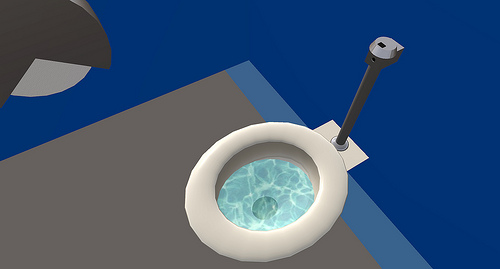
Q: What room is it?
A: It is a bathroom.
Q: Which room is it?
A: It is a bathroom.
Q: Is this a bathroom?
A: Yes, it is a bathroom.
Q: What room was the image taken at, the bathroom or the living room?
A: It was taken at the bathroom.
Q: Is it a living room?
A: No, it is a bathroom.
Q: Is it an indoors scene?
A: Yes, it is indoors.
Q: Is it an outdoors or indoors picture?
A: It is indoors.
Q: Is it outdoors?
A: No, it is indoors.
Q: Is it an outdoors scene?
A: No, it is indoors.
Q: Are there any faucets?
A: No, there are no faucets.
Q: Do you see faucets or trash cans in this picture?
A: No, there are no faucets or trash cans.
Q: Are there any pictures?
A: No, there are no pictures.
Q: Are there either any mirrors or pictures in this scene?
A: No, there are no pictures or mirrors.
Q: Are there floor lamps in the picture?
A: No, there are no floor lamps.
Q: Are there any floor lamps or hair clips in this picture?
A: No, there are no floor lamps or hair clips.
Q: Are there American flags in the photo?
A: No, there are no American flags.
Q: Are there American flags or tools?
A: No, there are no American flags or tools.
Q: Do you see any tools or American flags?
A: No, there are no American flags or tools.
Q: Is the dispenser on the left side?
A: Yes, the dispenser is on the left of the image.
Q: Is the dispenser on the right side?
A: No, the dispenser is on the left of the image.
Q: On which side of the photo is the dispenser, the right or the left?
A: The dispenser is on the left of the image.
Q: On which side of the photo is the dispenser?
A: The dispenser is on the left of the image.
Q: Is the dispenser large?
A: Yes, the dispenser is large.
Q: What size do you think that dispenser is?
A: The dispenser is large.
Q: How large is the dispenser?
A: The dispenser is large.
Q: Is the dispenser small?
A: No, the dispenser is large.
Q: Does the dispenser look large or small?
A: The dispenser is large.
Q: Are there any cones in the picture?
A: No, there are no cones.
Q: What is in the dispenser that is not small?
A: The paper is in the dispenser.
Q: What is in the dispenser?
A: The paper is in the dispenser.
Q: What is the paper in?
A: The paper is in the dispenser.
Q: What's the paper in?
A: The paper is in the dispenser.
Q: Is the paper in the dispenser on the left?
A: Yes, the paper is in the dispenser.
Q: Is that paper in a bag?
A: No, the paper is in the dispenser.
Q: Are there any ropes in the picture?
A: No, there are no ropes.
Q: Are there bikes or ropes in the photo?
A: No, there are no ropes or bikes.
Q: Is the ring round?
A: Yes, the ring is round.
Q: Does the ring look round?
A: Yes, the ring is round.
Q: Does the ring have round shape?
A: Yes, the ring is round.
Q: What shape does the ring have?
A: The ring has round shape.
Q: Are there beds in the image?
A: No, there are no beds.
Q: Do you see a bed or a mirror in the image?
A: No, there are no beds or mirrors.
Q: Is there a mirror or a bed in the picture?
A: No, there are no beds or mirrors.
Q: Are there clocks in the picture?
A: No, there are no clocks.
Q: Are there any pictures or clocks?
A: No, there are no clocks or pictures.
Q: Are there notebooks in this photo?
A: No, there are no notebooks.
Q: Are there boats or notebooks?
A: No, there are no notebooks or boats.